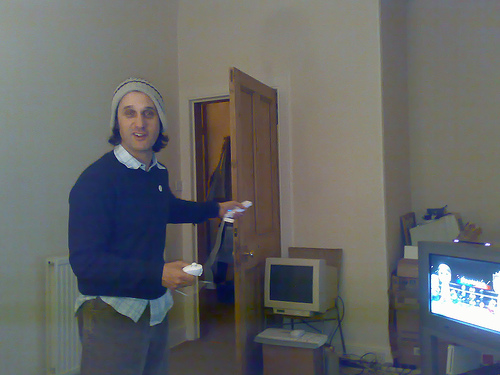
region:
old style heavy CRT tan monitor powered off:
[261, 252, 338, 317]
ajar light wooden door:
[231, 67, 278, 373]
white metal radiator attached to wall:
[43, 257, 79, 372]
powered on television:
[418, 242, 498, 357]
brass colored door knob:
[236, 244, 256, 266]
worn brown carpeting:
[170, 347, 236, 372]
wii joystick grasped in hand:
[166, 257, 203, 295]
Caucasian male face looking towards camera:
[105, 73, 172, 159]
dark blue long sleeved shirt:
[66, 150, 220, 300]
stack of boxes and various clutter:
[392, 208, 479, 365]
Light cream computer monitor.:
[265, 258, 342, 318]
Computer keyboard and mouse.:
[253, 323, 328, 350]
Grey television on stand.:
[416, 238, 498, 337]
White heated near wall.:
[45, 248, 81, 370]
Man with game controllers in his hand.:
[65, 65, 254, 373]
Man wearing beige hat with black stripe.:
[67, 68, 257, 373]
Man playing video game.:
[62, 76, 257, 373]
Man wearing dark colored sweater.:
[68, 68, 253, 374]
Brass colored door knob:
[243, 246, 255, 261]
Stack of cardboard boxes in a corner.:
[388, 206, 482, 364]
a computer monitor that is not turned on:
[261, 255, 340, 317]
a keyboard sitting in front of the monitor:
[252, 323, 329, 350]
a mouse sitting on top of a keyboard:
[287, 325, 307, 344]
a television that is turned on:
[414, 238, 498, 354]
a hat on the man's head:
[103, 75, 171, 135]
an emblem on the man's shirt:
[155, 181, 165, 195]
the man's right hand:
[159, 260, 201, 295]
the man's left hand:
[218, 193, 247, 221]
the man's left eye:
[141, 106, 156, 119]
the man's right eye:
[123, 106, 137, 117]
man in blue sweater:
[67, 76, 242, 371]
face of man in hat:
[107, 76, 169, 156]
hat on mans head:
[108, 77, 170, 136]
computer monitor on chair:
[261, 253, 338, 316]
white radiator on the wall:
[45, 256, 90, 373]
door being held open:
[182, 65, 267, 370]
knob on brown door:
[237, 249, 257, 261]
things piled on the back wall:
[396, 208, 476, 242]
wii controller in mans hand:
[178, 260, 206, 285]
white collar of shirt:
[110, 142, 142, 173]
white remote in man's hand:
[165, 252, 227, 310]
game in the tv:
[415, 243, 497, 355]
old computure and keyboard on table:
[240, 253, 342, 358]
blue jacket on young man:
[58, 123, 219, 305]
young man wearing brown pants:
[49, 297, 199, 374]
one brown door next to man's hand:
[214, 61, 284, 373]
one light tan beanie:
[104, 73, 171, 160]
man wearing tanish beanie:
[104, 88, 186, 158]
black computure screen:
[269, 252, 329, 316]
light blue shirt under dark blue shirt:
[74, 278, 203, 343]